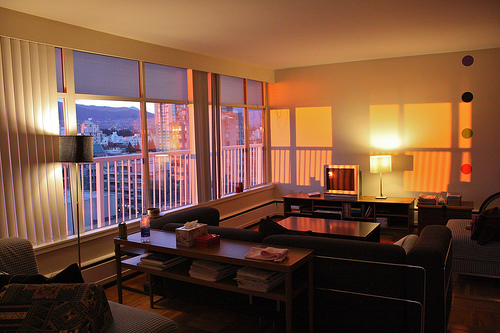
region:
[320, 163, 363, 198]
Television.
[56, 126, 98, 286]
Floor lamp, turned on.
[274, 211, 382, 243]
Coffee table.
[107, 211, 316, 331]
Sofa table with items on it.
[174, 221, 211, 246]
Open box of tissues.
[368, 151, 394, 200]
Table lamp that is turned on.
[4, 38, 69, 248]
White vertical blinds.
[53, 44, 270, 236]
View from inside the apartment.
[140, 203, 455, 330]
Modern looking sofa.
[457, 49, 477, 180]
Four circular discs hanging on the wall.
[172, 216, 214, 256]
box of tissues on table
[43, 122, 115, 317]
lamp closest to the window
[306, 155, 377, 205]
computer on stand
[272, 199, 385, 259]
coffee table opposite tv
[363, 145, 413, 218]
lamp near to the tv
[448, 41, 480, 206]
colored dots on the wall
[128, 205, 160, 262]
water bottle on table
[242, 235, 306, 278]
cloth on table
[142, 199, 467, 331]
large sofa opposite tv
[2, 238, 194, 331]
char nearest the window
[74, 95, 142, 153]
a window on a house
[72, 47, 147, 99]
a window on a house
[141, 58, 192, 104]
a window on a house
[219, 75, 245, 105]
a window on a house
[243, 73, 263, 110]
a window on a house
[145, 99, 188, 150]
a window on a house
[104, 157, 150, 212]
a window on a house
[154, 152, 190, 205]
a window on a house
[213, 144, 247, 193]
a window on a house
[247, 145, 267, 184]
a window on a house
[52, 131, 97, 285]
floor lamp with dark shade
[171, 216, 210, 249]
box of tissues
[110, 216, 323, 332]
sofa table with shelf of reading materials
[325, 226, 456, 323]
sofa with metal frame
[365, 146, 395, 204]
table lamp with white shade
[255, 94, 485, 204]
sunset reflected against wall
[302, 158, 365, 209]
television and remote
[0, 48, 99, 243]
open white vertical blinds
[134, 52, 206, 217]
window with a view of a city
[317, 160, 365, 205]
television turned off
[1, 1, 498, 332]
a picture of an apartment living room apartment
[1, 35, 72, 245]
beige vertical blinds on the window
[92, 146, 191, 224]
metal railing on a balcony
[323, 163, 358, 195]
a TV on top of a table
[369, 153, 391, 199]
a table lamp next to the TV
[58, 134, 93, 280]
a floor lamp with a green shade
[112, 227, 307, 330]
a wooden sofa table with shelves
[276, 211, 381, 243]
a coffee table in the center of the room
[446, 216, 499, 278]
a grey ottoman chair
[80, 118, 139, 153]
buildings outside in the distance